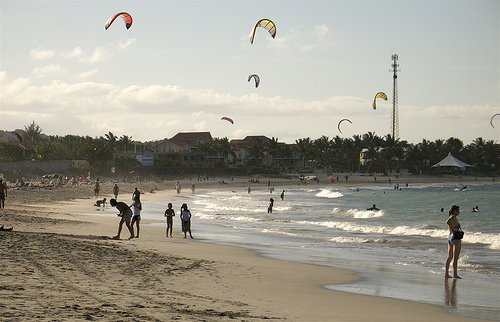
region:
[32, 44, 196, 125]
the sky is cloudy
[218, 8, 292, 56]
the kite is flying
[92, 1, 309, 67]
there are two kites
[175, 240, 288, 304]
the beach is brown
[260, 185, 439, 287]
the waves are small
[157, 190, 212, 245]
the people are standing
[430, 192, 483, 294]
the girl is standing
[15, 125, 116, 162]
the trees are green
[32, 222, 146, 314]
the sand is rough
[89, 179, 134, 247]
the man is bending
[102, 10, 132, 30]
Kite in the sky.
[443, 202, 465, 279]
Woman standing on the beach.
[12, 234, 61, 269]
Divots in the sand.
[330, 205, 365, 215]
Waves in the water.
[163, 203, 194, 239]
Two people standing in the sand.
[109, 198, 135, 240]
Person bent over in the sand.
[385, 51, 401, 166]
Large metal tower in the distance.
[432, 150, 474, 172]
Large white canopy.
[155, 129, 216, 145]
Roof of a building.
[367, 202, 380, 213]
Person in the water.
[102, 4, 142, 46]
orange and black kite sail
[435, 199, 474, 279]
woman in a bikini with a black bag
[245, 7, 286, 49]
yellow and black kite sail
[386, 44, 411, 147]
tall metal communication tower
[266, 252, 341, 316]
smooth tan sandy beach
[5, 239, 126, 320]
rough tan sand with many footprints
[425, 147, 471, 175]
white tent top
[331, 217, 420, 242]
white crest of a wave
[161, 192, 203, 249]
two children standing on the beach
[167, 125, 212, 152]
red roof of a building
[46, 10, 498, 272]
parasailers above a beach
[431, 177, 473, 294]
woman in blue bikini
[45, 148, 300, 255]
people on the beach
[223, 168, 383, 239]
people playing in the water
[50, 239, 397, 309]
sandy beach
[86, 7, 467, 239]
people gliding above the beach and people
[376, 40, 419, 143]
large cell phone tower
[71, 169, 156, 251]
man crouching on the beach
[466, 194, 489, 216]
people in the water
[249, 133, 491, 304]
waves coming in on the beach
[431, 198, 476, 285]
Woman standing on the beach.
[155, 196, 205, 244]
Two children standing near the water's edge.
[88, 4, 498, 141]
Seven kites in the sky.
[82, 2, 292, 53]
An orange kite and a yellow kite in the sky.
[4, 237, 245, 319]
Sand on the beach.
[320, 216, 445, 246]
Waves coming in to shore.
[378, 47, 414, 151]
Cell phone tower in the distance.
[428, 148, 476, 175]
Building with a white roof.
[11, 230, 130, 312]
Tracks in the sand.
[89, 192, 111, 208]
Person kneeling down on the sand.